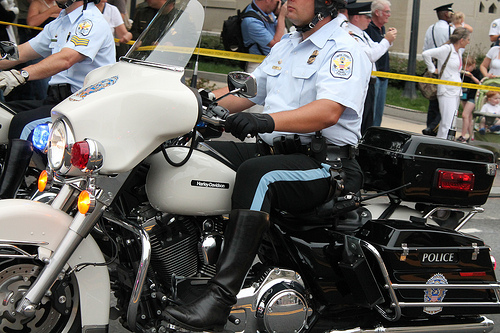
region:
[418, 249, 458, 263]
writing on the back of a motorcycle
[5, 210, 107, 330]
the front tire to a chopper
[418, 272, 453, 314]
a police logo on the back of a chopper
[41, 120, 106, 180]
the headlights to a police chopper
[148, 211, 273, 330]
black leather boots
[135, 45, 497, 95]
a line of yellow caution tape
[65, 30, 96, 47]
a badge of rank on a mans shoulder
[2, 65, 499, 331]
a police motorcycle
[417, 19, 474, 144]
a woman dressed in white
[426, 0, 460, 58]
a police officer wearing a black cap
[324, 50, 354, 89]
a patch on the shrt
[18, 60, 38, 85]
a man wearing a watch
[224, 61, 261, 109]
a mirror on the motorcycle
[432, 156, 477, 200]
a light on the motorcycle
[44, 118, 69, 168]
headlight on a motorcycle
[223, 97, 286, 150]
a pair of black gloves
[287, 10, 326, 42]
a strap to a helmet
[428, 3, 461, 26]
a man with a hat on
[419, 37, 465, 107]
a woman carrying a purse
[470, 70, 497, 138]
a kid in a stroller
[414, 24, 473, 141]
woman carrying shoulder bag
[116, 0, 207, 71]
motorcycle windshield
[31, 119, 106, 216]
front lights of police motorcycle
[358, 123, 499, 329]
two black luggage compartments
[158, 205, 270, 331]
calf-high black leather boots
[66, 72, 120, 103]
police shield decal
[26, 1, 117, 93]
shirt with emblem and stripes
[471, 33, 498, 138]
woman with toddler in a stroller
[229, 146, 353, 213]
black pants with blue side stripe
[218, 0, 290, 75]
man carrying a backpack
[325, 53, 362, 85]
patch on the shirt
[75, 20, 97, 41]
patch on the shirt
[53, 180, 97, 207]
light on the motorcycle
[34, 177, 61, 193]
light on the motorcycle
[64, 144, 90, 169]
light on the motorcycle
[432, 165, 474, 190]
light on the motorcycle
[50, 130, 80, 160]
light on the motorcycle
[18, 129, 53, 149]
light on the motorcycle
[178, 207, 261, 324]
boot on the rider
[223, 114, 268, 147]
glove on the rider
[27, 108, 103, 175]
light on the front of the bike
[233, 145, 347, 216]
blue and black pant leg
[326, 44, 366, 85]
symbol on side of shirt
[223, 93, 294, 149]
glove on the hand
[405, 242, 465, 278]
word on the bike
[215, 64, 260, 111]
rearview mirror on the bike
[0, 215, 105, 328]
tire on the bike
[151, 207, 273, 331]
boot on the man's leg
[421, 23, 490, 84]
woman in the background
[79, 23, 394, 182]
two people next to each other